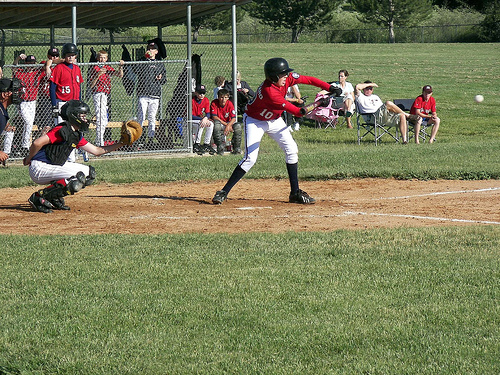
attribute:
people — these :
[117, 22, 435, 174]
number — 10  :
[257, 108, 272, 120]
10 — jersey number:
[259, 108, 276, 118]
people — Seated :
[351, 73, 388, 140]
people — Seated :
[413, 81, 441, 143]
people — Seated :
[326, 63, 356, 130]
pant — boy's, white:
[219, 109, 339, 175]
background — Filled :
[15, 18, 435, 373]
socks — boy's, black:
[221, 164, 246, 196]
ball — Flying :
[474, 94, 485, 104]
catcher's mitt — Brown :
[117, 115, 147, 145]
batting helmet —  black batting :
[270, 83, 385, 130]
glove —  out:
[118, 120, 145, 144]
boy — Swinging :
[210, 49, 339, 214]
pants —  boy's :
[234, 107, 299, 189]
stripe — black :
[236, 108, 251, 171]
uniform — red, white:
[237, 70, 329, 172]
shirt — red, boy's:
[252, 69, 311, 127]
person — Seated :
[342, 78, 414, 153]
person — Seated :
[397, 71, 448, 143]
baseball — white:
[473, 90, 487, 104]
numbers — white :
[56, 78, 74, 102]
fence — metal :
[5, 55, 194, 156]